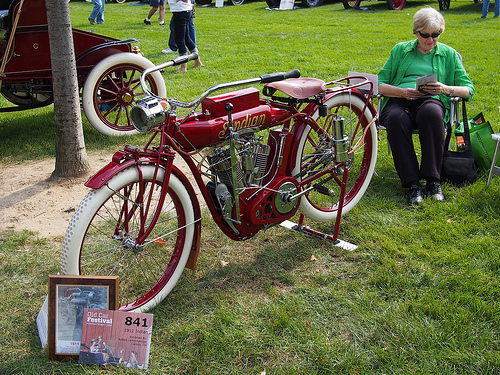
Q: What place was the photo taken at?
A: It was taken at the field.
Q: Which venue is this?
A: This is a field.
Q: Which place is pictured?
A: It is a field.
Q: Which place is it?
A: It is a field.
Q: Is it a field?
A: Yes, it is a field.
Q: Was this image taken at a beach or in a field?
A: It was taken at a field.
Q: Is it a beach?
A: No, it is a field.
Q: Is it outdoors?
A: Yes, it is outdoors.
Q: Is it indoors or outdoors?
A: It is outdoors.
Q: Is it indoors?
A: No, it is outdoors.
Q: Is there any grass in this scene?
A: Yes, there is grass.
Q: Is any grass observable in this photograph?
A: Yes, there is grass.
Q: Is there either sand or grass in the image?
A: Yes, there is grass.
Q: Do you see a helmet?
A: No, there are no helmets.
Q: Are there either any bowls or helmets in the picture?
A: No, there are no helmets or bowls.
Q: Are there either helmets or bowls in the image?
A: No, there are no helmets or bowls.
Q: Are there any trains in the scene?
A: No, there are no trains.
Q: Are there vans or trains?
A: No, there are no trains or vans.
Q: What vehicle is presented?
A: The vehicle is a car.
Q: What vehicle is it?
A: The vehicle is a car.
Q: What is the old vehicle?
A: The vehicle is a car.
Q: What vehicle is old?
A: The vehicle is a car.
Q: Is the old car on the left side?
A: Yes, the car is on the left of the image.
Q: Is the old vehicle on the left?
A: Yes, the car is on the left of the image.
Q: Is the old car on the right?
A: No, the car is on the left of the image.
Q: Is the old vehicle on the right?
A: No, the car is on the left of the image.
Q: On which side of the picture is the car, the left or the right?
A: The car is on the left of the image.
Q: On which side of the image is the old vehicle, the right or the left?
A: The car is on the left of the image.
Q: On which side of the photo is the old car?
A: The car is on the left of the image.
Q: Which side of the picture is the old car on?
A: The car is on the left of the image.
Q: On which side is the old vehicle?
A: The car is on the left of the image.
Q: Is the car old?
A: Yes, the car is old.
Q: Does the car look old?
A: Yes, the car is old.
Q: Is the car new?
A: No, the car is old.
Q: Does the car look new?
A: No, the car is old.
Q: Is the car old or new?
A: The car is old.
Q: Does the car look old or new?
A: The car is old.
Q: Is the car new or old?
A: The car is old.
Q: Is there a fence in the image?
A: No, there are no fences.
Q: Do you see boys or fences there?
A: No, there are no fences or boys.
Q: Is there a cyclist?
A: No, there are no cyclists.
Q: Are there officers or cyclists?
A: No, there are no cyclists or officers.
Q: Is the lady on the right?
A: Yes, the lady is on the right of the image.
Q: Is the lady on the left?
A: No, the lady is on the right of the image.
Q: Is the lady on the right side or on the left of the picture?
A: The lady is on the right of the image.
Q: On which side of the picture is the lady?
A: The lady is on the right of the image.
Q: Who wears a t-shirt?
A: The lady wears a t-shirt.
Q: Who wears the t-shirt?
A: The lady wears a t-shirt.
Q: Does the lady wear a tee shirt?
A: Yes, the lady wears a tee shirt.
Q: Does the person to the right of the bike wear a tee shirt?
A: Yes, the lady wears a tee shirt.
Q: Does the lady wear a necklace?
A: No, the lady wears a tee shirt.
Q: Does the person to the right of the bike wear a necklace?
A: No, the lady wears a tee shirt.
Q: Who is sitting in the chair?
A: The lady is sitting in the chair.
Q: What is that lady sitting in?
A: The lady is sitting in the chair.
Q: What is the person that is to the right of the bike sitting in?
A: The lady is sitting in the chair.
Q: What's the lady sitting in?
A: The lady is sitting in the chair.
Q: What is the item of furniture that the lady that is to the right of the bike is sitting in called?
A: The piece of furniture is a chair.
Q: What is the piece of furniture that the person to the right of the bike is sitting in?
A: The piece of furniture is a chair.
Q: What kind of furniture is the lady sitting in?
A: The lady is sitting in the chair.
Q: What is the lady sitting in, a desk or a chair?
A: The lady is sitting in a chair.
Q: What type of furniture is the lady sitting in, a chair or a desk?
A: The lady is sitting in a chair.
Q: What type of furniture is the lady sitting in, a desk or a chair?
A: The lady is sitting in a chair.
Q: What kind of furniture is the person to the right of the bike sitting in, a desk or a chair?
A: The lady is sitting in a chair.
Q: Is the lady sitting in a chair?
A: Yes, the lady is sitting in a chair.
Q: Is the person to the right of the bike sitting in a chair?
A: Yes, the lady is sitting in a chair.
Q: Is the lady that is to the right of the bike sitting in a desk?
A: No, the lady is sitting in a chair.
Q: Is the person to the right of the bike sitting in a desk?
A: No, the lady is sitting in a chair.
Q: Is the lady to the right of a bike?
A: Yes, the lady is to the right of a bike.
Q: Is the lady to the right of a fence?
A: No, the lady is to the right of a bike.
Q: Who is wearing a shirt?
A: The lady is wearing a shirt.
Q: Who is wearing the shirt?
A: The lady is wearing a shirt.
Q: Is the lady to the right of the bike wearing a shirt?
A: Yes, the lady is wearing a shirt.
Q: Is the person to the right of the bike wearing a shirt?
A: Yes, the lady is wearing a shirt.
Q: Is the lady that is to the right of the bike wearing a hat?
A: No, the lady is wearing a shirt.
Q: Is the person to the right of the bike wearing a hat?
A: No, the lady is wearing a shirt.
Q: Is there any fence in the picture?
A: No, there are no fences.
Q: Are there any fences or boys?
A: No, there are no fences or boys.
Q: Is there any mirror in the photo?
A: No, there are no mirrors.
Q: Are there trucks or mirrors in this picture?
A: No, there are no mirrors or trucks.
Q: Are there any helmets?
A: No, there are no helmets.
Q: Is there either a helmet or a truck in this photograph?
A: No, there are no helmets or trucks.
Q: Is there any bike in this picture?
A: Yes, there is a bike.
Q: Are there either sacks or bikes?
A: Yes, there is a bike.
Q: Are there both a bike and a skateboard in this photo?
A: No, there is a bike but no skateboards.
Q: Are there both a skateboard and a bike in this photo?
A: No, there is a bike but no skateboards.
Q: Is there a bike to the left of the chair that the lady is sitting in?
A: Yes, there is a bike to the left of the chair.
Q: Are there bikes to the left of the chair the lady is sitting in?
A: Yes, there is a bike to the left of the chair.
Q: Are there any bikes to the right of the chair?
A: No, the bike is to the left of the chair.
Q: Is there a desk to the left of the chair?
A: No, there is a bike to the left of the chair.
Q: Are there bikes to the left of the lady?
A: Yes, there is a bike to the left of the lady.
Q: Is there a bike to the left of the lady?
A: Yes, there is a bike to the left of the lady.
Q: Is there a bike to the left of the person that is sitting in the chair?
A: Yes, there is a bike to the left of the lady.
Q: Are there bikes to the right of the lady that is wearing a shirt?
A: No, the bike is to the left of the lady.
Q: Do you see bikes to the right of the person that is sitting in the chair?
A: No, the bike is to the left of the lady.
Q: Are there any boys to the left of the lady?
A: No, there is a bike to the left of the lady.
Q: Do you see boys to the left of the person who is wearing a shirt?
A: No, there is a bike to the left of the lady.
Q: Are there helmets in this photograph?
A: No, there are no helmets.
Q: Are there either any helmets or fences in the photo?
A: No, there are no helmets or fences.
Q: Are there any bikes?
A: Yes, there is a bike.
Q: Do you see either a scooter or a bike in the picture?
A: Yes, there is a bike.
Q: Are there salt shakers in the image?
A: No, there are no salt shakers.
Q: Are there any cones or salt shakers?
A: No, there are no salt shakers or cones.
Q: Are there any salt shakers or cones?
A: No, there are no salt shakers or cones.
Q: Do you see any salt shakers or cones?
A: No, there are no salt shakers or cones.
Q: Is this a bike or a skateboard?
A: This is a bike.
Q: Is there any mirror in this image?
A: No, there are no mirrors.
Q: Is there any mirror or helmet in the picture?
A: No, there are no mirrors or helmets.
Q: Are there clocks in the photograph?
A: No, there are no clocks.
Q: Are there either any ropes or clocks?
A: No, there are no clocks or ropes.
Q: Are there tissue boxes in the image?
A: No, there are no tissue boxes.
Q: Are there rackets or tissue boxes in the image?
A: No, there are no tissue boxes or rackets.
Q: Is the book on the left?
A: Yes, the book is on the left of the image.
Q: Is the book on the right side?
A: No, the book is on the left of the image.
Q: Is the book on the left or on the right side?
A: The book is on the left of the image.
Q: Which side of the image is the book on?
A: The book is on the left of the image.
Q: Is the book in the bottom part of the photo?
A: Yes, the book is in the bottom of the image.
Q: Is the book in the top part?
A: No, the book is in the bottom of the image.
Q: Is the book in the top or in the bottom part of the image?
A: The book is in the bottom of the image.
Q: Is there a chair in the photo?
A: Yes, there is a chair.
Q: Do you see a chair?
A: Yes, there is a chair.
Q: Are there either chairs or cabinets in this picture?
A: Yes, there is a chair.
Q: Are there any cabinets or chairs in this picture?
A: Yes, there is a chair.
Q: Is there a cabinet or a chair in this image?
A: Yes, there is a chair.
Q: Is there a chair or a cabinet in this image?
A: Yes, there is a chair.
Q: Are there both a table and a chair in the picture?
A: No, there is a chair but no tables.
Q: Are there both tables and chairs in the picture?
A: No, there is a chair but no tables.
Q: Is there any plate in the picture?
A: No, there are no plates.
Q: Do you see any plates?
A: No, there are no plates.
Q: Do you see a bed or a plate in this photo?
A: No, there are no plates or beds.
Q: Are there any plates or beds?
A: No, there are no plates or beds.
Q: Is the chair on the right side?
A: Yes, the chair is on the right of the image.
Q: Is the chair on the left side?
A: No, the chair is on the right of the image.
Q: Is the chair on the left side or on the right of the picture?
A: The chair is on the right of the image.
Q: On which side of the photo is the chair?
A: The chair is on the right of the image.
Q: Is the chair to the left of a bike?
A: No, the chair is to the right of a bike.